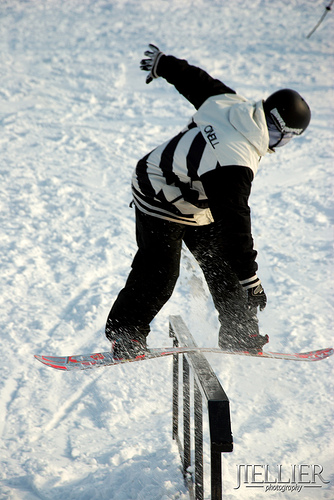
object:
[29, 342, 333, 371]
snowboard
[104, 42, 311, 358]
person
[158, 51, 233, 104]
arm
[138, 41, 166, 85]
hand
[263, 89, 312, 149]
helmet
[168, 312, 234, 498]
railing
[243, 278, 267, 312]
glove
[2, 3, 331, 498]
snow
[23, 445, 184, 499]
shadow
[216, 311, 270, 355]
boot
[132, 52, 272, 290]
jacket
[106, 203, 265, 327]
pants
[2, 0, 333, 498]
ground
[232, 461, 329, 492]
label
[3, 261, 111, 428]
tracks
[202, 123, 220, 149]
wording